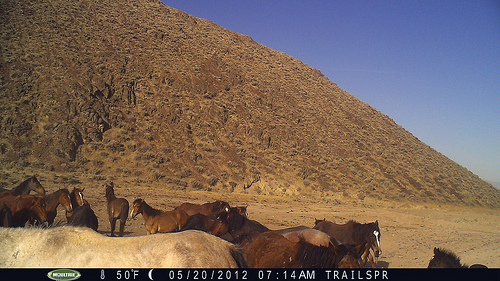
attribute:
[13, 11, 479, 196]
hill — brown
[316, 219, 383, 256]
horse — brown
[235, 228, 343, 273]
horse — brown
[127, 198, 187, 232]
horse — brown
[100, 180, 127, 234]
horse — brown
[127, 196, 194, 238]
horse — golden brown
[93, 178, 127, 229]
horse — brown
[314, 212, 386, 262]
horse — brown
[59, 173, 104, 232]
horse — brown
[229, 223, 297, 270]
horse — brown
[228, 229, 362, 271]
horse — brown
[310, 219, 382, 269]
horse — brown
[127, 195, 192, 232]
horse — brown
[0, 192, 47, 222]
horse — brown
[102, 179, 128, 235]
horse — large, herd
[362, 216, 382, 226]
ears — brown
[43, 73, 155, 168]
outcrop — rocky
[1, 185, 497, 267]
ground — brown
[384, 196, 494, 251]
dessert — brown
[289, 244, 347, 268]
mane — black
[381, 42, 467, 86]
sky — blue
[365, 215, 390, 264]
head — horse's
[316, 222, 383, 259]
horse — brown, white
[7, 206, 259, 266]
horse — grayish, white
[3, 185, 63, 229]
horse — brown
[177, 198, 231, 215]
horse — brown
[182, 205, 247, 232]
horse — brown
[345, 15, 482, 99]
sky — patch, clear, blue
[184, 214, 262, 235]
horse — brown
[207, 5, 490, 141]
sky — blue, white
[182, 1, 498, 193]
sky — blue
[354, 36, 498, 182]
clouds — white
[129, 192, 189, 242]
horse — brown